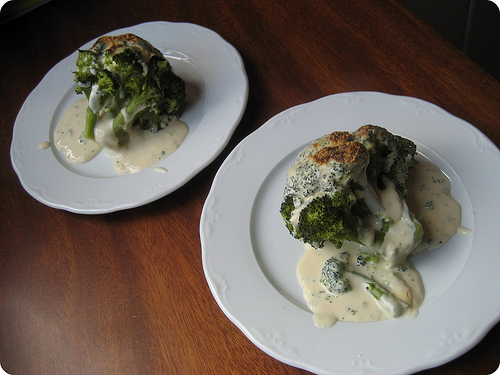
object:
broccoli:
[280, 130, 385, 249]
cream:
[412, 162, 462, 251]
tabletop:
[4, 4, 499, 374]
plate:
[199, 90, 499, 374]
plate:
[9, 21, 251, 216]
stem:
[380, 216, 423, 266]